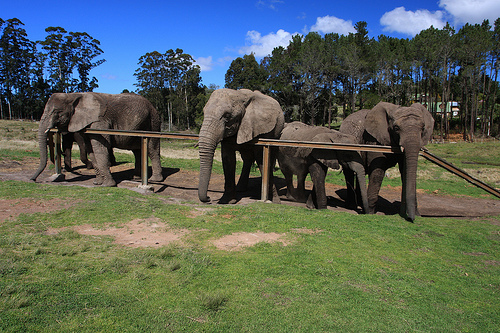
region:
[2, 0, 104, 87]
trees in bright blue sky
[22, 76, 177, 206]
large dirty elephant on rail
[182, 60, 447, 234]
herd of elephants on rail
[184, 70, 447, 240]
two adult and one baby elephant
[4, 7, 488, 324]
elephants in open field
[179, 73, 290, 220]
elephant with large ears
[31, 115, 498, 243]
old rusty support rail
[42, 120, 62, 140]
small white elephant tusk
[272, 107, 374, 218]
baby elephant behind rail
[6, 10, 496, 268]
elephants behind a rusty rail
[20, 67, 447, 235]
some gray elephants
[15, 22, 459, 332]
a scene outside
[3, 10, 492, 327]
a scene happening during the day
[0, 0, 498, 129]
a sky with some clouds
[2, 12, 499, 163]
a row of trees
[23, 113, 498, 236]
a brown rail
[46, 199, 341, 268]
some dirt patches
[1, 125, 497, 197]
a trail behind the elephants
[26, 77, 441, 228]
a group of animals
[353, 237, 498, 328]
some green grass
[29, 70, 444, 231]
a row of gray elephants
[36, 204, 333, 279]
couple of dirt patches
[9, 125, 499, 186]
a trail behind the elephants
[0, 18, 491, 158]
a row of green trees in the background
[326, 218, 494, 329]
a green field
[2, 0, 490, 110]
sky with some clouds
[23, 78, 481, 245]
some animals standing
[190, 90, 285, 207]
elephant with trunk on ground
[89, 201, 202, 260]
patch of dirt in grass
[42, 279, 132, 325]
dark green grass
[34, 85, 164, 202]
elephant standing on dirt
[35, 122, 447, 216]
wooden brown fence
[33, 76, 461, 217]
elephants standing behind wooden fence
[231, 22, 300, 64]
large white fluffy clouds in sky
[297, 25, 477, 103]
trees with green leaves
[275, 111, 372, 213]
small elephant between two larger ones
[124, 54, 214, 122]
tree behind elephants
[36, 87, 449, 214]
three adult African elephants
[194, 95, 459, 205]
Juvenile African elephant with adults.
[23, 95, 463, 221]
four elephants behind steel barrier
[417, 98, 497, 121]
blue building behind trees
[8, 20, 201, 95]
tall trees with blue skies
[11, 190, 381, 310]
green grass with bald dirt patches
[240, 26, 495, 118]
tree line hiding animal enclosure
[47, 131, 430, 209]
rusty steel retaining barrier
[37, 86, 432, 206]
captive elephants in the sun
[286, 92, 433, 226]
mother elephant with juvenile